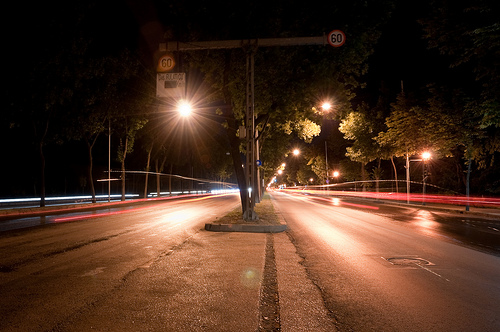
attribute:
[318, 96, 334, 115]
light — yellow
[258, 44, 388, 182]
trees — green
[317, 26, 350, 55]
sign — round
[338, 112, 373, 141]
leaves — green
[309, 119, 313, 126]
leaf — green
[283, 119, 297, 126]
leaf — green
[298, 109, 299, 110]
leaf — green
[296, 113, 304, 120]
leaf — green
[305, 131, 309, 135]
leaf — green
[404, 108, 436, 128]
leaves — green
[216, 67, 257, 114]
leaves — green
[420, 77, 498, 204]
tree — green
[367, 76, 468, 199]
tree — green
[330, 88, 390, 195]
tree — green